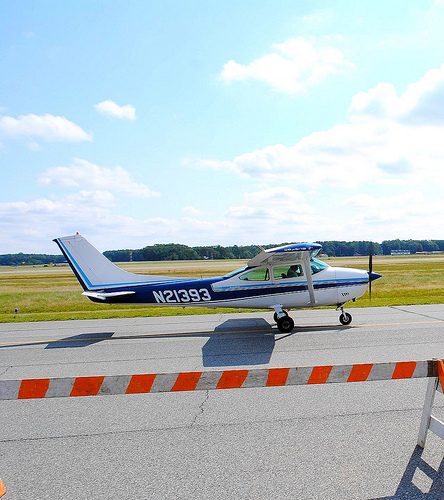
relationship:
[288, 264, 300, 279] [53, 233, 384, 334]
man on plane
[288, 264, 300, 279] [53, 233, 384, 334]
man in plane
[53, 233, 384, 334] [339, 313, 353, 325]
plane has wheel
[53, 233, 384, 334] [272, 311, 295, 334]
plane has wheels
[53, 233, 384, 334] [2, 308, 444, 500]
plane on tarmac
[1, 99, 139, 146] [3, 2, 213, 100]
clouds in sky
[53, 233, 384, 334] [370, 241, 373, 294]
plane has propeller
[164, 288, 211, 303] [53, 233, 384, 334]
number on plane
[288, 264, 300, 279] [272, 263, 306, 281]
man in cockpit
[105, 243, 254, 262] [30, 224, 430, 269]
trees in background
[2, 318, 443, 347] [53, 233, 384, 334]
line under plane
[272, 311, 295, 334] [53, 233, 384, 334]
wheels under plane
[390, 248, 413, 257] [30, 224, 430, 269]
buildings in background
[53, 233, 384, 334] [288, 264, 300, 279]
plane has man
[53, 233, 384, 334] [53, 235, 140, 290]
plane with tail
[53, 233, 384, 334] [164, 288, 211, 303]
plane with number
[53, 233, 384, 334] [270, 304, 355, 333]
plane has landing gear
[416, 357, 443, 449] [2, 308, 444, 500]
sawhorse on tarmac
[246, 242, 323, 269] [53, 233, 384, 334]
wing of plane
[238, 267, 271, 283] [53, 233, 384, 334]
window on plane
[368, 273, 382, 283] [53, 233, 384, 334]
nose of plane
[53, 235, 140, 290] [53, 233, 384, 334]
tail of plane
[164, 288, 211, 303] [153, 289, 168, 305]
number and letter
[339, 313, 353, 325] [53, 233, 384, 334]
wheel on plane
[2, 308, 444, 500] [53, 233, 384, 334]
tarmac under plane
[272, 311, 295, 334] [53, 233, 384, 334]
wheels on plane